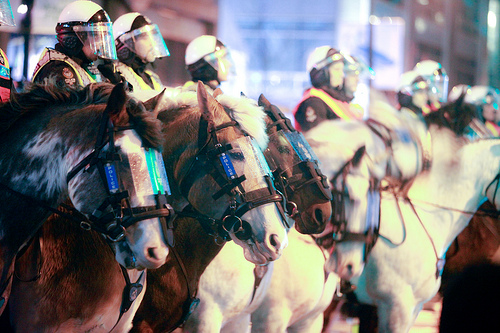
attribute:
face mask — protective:
[70, 21, 119, 61]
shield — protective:
[100, 147, 171, 196]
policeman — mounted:
[33, 1, 119, 91]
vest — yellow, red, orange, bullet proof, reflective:
[30, 48, 96, 87]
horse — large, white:
[351, 136, 500, 331]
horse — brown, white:
[1, 81, 173, 305]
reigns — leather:
[3, 184, 109, 236]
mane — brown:
[2, 80, 166, 152]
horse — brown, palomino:
[137, 82, 288, 265]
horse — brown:
[140, 89, 333, 304]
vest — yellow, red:
[113, 62, 161, 92]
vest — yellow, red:
[291, 87, 354, 132]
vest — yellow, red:
[1, 47, 13, 104]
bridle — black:
[63, 102, 179, 245]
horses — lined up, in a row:
[1, 81, 500, 333]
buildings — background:
[2, 2, 500, 135]